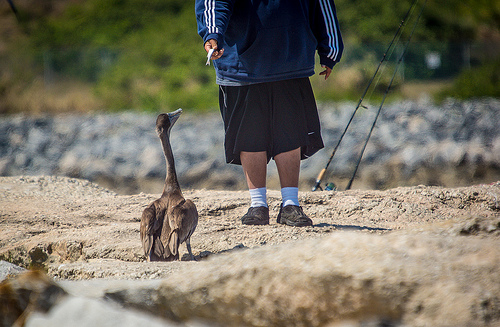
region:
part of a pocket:
[256, 38, 291, 63]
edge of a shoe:
[288, 209, 308, 238]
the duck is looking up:
[139, 95, 195, 193]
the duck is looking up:
[127, 73, 216, 239]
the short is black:
[189, 25, 344, 194]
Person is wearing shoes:
[239, 201, 312, 229]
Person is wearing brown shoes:
[237, 203, 315, 228]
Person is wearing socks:
[242, 183, 302, 208]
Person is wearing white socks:
[243, 182, 303, 209]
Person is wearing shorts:
[215, 67, 330, 164]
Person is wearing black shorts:
[215, 74, 327, 167]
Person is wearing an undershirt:
[210, 62, 325, 89]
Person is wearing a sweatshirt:
[191, 0, 352, 79]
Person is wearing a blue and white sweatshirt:
[190, 0, 346, 81]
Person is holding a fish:
[201, 44, 218, 66]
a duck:
[132, 106, 228, 271]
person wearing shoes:
[242, 201, 283, 229]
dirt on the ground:
[22, 194, 117, 240]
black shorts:
[225, 95, 305, 140]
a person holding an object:
[195, 36, 233, 68]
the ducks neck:
[152, 146, 190, 186]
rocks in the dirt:
[17, 170, 68, 190]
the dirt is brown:
[45, 200, 129, 245]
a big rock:
[240, 248, 370, 308]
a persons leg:
[241, 153, 268, 188]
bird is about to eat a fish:
[141, 105, 197, 260]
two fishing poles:
[310, 1, 423, 193]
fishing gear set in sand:
[313, 1, 420, 191]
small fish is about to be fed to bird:
[206, 43, 215, 65]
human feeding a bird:
[195, 4, 346, 226]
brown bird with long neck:
[139, 107, 198, 256]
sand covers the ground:
[1, 177, 498, 319]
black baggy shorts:
[215, 72, 326, 164]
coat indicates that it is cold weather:
[193, 0, 342, 78]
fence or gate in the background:
[1, 39, 498, 87]